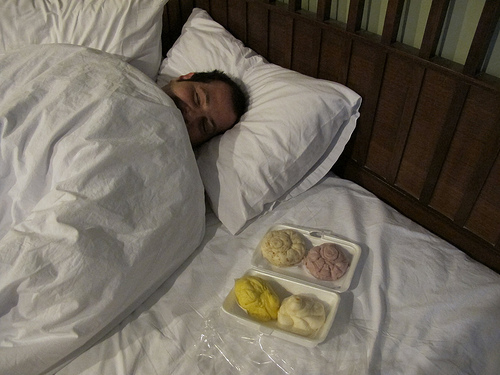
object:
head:
[160, 67, 248, 143]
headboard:
[158, 0, 498, 273]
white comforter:
[1, 42, 186, 372]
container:
[219, 221, 361, 346]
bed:
[0, 0, 496, 372]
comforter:
[0, 45, 208, 373]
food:
[302, 238, 348, 279]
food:
[260, 225, 309, 267]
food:
[277, 292, 327, 337]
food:
[234, 274, 278, 319]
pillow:
[148, 7, 367, 236]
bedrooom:
[0, 0, 497, 373]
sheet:
[417, 241, 444, 307]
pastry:
[232, 229, 350, 335]